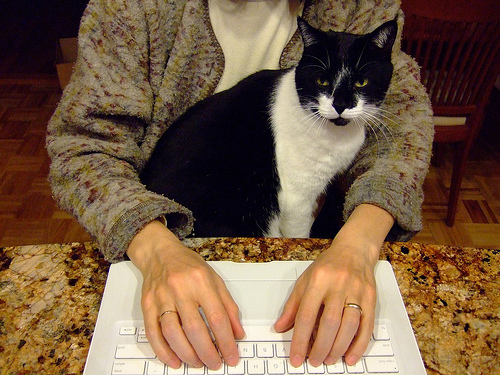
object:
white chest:
[273, 113, 364, 178]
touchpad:
[215, 280, 296, 324]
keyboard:
[107, 325, 400, 375]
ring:
[342, 303, 363, 314]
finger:
[308, 301, 342, 367]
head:
[293, 13, 398, 127]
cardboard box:
[60, 39, 78, 63]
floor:
[0, 3, 500, 243]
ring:
[159, 310, 177, 318]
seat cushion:
[432, 115, 466, 126]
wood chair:
[396, 13, 498, 227]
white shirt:
[206, 0, 304, 97]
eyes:
[316, 76, 330, 86]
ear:
[371, 20, 397, 49]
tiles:
[461, 199, 499, 225]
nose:
[331, 102, 348, 116]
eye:
[352, 76, 370, 89]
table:
[2, 236, 499, 373]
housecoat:
[43, 0, 435, 264]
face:
[296, 44, 390, 126]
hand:
[273, 245, 377, 367]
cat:
[137, 16, 399, 238]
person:
[43, 0, 435, 371]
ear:
[296, 14, 323, 44]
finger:
[156, 305, 199, 369]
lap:
[124, 201, 408, 250]